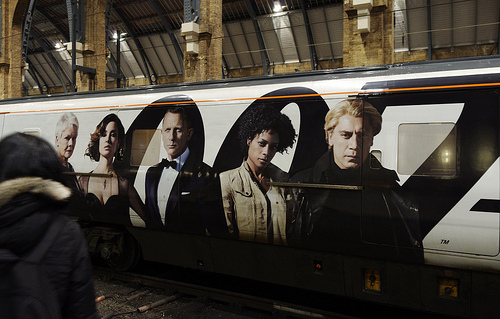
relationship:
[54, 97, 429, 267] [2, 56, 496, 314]
people on side of train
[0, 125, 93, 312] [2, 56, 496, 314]
person outside of train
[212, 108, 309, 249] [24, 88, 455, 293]
actor on advertisement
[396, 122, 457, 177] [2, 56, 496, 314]
window on train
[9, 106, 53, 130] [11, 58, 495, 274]
white paint on train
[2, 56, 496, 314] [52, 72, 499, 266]
train with an advertisement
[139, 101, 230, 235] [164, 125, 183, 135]
man has eyes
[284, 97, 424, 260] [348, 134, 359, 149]
man has nose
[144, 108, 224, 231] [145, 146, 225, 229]
man in a suit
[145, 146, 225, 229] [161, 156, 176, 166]
suit and bow tie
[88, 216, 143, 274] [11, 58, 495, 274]
wheel on train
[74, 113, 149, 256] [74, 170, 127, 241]
woman in dress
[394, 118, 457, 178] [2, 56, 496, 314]
window on train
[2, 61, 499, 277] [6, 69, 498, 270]
advertisement for james bond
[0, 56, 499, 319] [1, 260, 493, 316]
train on tracks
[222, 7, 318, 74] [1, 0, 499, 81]
window in building